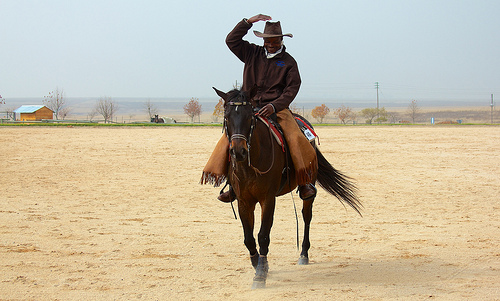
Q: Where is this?
A: This is at the field.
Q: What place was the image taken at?
A: It was taken at the field.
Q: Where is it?
A: This is at the field.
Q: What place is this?
A: It is a field.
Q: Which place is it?
A: It is a field.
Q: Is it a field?
A: Yes, it is a field.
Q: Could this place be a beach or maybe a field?
A: It is a field.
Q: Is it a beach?
A: No, it is a field.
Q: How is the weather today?
A: It is overcast.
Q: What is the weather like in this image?
A: It is overcast.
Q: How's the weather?
A: It is overcast.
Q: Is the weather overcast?
A: Yes, it is overcast.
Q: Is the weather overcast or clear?
A: It is overcast.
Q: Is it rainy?
A: No, it is overcast.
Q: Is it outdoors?
A: Yes, it is outdoors.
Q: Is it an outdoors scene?
A: Yes, it is outdoors.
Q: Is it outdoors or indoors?
A: It is outdoors.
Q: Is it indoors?
A: No, it is outdoors.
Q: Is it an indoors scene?
A: No, it is outdoors.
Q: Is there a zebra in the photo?
A: No, there are no zebras.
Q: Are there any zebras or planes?
A: No, there are no zebras or planes.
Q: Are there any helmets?
A: No, there are no helmets.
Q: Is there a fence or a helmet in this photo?
A: No, there are no helmets or fences.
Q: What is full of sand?
A: The field is full of sand.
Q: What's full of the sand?
A: The field is full of sand.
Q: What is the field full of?
A: The field is full of sand.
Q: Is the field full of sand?
A: Yes, the field is full of sand.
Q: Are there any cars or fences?
A: No, there are no fences or cars.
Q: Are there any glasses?
A: No, there are no glasses.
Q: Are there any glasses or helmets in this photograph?
A: No, there are no glasses or helmets.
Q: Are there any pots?
A: No, there are no pots.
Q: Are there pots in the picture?
A: No, there are no pots.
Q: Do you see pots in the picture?
A: No, there are no pots.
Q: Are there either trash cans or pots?
A: No, there are no pots or trash cans.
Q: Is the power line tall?
A: Yes, the power line is tall.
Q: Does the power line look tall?
A: Yes, the power line is tall.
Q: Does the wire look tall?
A: Yes, the wire is tall.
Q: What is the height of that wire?
A: The wire is tall.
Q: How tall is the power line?
A: The power line is tall.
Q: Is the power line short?
A: No, the power line is tall.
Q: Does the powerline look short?
A: No, the powerline is tall.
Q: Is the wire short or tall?
A: The wire is tall.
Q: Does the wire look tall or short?
A: The wire is tall.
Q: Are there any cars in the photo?
A: No, there are no cars.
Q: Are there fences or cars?
A: No, there are no cars or fences.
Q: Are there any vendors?
A: No, there are no vendors.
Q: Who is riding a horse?
A: The cowboy is riding a horse.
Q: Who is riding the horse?
A: The cowboy is riding a horse.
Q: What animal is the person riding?
A: The cowboy is riding a horse.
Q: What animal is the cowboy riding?
A: The cowboy is riding a horse.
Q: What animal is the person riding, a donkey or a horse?
A: The cowboy is riding a horse.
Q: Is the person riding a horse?
A: Yes, the cowboy is riding a horse.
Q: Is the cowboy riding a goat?
A: No, the cowboy is riding a horse.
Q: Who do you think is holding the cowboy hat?
A: The cowboy is holding the cowboy hat.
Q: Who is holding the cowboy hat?
A: The cowboy is holding the cowboy hat.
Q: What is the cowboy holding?
A: The cowboy is holding the cowboy hat.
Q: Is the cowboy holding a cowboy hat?
A: Yes, the cowboy is holding a cowboy hat.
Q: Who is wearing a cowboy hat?
A: The cowboy is wearing a cowboy hat.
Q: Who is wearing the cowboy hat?
A: The cowboy is wearing a cowboy hat.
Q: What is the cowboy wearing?
A: The cowboy is wearing a cowboy hat.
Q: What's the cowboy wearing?
A: The cowboy is wearing a cowboy hat.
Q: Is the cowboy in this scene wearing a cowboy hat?
A: Yes, the cowboy is wearing a cowboy hat.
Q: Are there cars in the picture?
A: No, there are no cars.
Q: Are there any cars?
A: No, there are no cars.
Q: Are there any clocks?
A: No, there are no clocks.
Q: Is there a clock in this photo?
A: No, there are no clocks.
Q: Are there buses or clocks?
A: No, there are no clocks or buses.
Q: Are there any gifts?
A: No, there are no gifts.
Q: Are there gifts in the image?
A: No, there are no gifts.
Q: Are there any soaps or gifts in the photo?
A: No, there are no gifts or soaps.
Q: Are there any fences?
A: No, there are no fences.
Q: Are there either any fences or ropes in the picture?
A: No, there are no fences or ropes.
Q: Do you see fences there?
A: No, there are no fences.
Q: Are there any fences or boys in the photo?
A: No, there are no fences or boys.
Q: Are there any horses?
A: Yes, there is a horse.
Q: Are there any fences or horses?
A: Yes, there is a horse.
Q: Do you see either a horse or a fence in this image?
A: Yes, there is a horse.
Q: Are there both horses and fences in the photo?
A: No, there is a horse but no fences.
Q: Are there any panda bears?
A: No, there are no panda bears.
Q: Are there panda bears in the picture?
A: No, there are no panda bears.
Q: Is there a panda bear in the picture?
A: No, there are no panda bears.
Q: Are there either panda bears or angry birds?
A: No, there are no panda bears or angry birds.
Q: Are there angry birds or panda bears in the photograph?
A: No, there are no panda bears or angry birds.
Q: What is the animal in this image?
A: The animal is a horse.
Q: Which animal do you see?
A: The animal is a horse.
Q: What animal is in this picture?
A: The animal is a horse.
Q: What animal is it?
A: The animal is a horse.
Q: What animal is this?
A: This is a horse.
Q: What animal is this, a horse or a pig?
A: This is a horse.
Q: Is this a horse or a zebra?
A: This is a horse.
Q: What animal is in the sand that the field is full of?
A: The horse is in the sand.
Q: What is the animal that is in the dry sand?
A: The animal is a horse.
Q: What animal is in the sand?
A: The animal is a horse.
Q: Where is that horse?
A: The horse is in the sand.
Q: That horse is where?
A: The horse is in the sand.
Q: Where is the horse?
A: The horse is in the sand.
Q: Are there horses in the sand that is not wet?
A: Yes, there is a horse in the sand.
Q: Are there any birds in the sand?
A: No, there is a horse in the sand.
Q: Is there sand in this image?
A: Yes, there is sand.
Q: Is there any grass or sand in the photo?
A: Yes, there is sand.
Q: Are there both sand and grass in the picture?
A: Yes, there are both sand and grass.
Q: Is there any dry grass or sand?
A: Yes, there is dry sand.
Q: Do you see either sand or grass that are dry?
A: Yes, the sand is dry.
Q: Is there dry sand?
A: Yes, there is dry sand.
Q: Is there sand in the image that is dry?
A: Yes, there is sand that is dry.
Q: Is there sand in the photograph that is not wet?
A: Yes, there is dry sand.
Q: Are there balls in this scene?
A: No, there are no balls.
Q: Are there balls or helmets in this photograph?
A: No, there are no balls or helmets.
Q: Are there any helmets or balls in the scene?
A: No, there are no balls or helmets.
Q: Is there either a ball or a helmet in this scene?
A: No, there are no balls or helmets.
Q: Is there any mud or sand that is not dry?
A: No, there is sand but it is dry.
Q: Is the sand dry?
A: Yes, the sand is dry.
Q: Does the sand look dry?
A: Yes, the sand is dry.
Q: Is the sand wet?
A: No, the sand is dry.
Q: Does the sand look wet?
A: No, the sand is dry.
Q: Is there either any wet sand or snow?
A: No, there is sand but it is dry.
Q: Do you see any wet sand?
A: No, there is sand but it is dry.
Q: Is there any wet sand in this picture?
A: No, there is sand but it is dry.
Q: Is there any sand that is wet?
A: No, there is sand but it is dry.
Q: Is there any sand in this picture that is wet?
A: No, there is sand but it is dry.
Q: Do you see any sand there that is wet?
A: No, there is sand but it is dry.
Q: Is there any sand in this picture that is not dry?
A: No, there is sand but it is dry.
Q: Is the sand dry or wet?
A: The sand is dry.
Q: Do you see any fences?
A: No, there are no fences.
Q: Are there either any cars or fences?
A: No, there are no fences or cars.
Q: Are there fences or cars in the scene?
A: No, there are no fences or cars.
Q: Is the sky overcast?
A: Yes, the sky is overcast.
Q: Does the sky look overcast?
A: Yes, the sky is overcast.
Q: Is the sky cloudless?
A: No, the sky is overcast.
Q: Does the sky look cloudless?
A: No, the sky is overcast.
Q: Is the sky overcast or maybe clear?
A: The sky is overcast.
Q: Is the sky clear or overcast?
A: The sky is overcast.